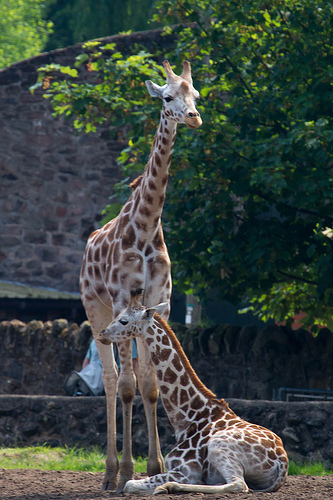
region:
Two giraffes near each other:
[76, 52, 291, 498]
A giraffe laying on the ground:
[95, 283, 294, 496]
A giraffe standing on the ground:
[77, 59, 188, 490]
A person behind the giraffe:
[73, 305, 143, 402]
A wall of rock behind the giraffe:
[5, 44, 162, 315]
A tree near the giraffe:
[47, 33, 331, 341]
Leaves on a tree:
[229, 109, 326, 301]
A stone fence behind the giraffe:
[4, 302, 330, 483]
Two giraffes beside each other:
[46, 37, 282, 497]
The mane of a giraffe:
[145, 305, 227, 401]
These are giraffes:
[45, 70, 209, 495]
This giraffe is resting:
[88, 314, 288, 480]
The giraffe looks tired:
[97, 315, 178, 354]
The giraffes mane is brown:
[153, 316, 231, 407]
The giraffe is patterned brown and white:
[157, 365, 238, 476]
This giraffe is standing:
[70, 68, 190, 271]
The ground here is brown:
[9, 464, 69, 497]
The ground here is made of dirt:
[33, 468, 83, 498]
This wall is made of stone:
[6, 336, 53, 403]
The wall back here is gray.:
[10, 133, 94, 277]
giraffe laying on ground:
[102, 301, 287, 492]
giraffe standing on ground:
[97, 67, 200, 485]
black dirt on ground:
[2, 469, 331, 494]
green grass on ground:
[2, 444, 321, 475]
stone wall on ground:
[4, 397, 330, 458]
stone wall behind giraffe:
[5, 325, 328, 402]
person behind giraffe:
[80, 340, 140, 391]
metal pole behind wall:
[274, 385, 331, 398]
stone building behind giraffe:
[0, 57, 196, 289]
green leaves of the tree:
[63, 70, 331, 324]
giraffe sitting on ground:
[95, 283, 288, 498]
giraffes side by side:
[80, 49, 295, 499]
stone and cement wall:
[0, 305, 332, 469]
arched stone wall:
[0, 26, 307, 311]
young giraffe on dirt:
[92, 287, 294, 497]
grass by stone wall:
[6, 391, 330, 479]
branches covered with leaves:
[65, 4, 331, 323]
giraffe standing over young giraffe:
[78, 61, 292, 491]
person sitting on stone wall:
[69, 315, 166, 409]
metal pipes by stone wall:
[264, 376, 331, 403]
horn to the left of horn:
[161, 59, 174, 75]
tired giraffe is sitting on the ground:
[95, 286, 288, 494]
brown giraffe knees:
[123, 388, 133, 402]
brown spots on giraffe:
[163, 368, 177, 383]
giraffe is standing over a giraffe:
[80, 58, 202, 492]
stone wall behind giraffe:
[0, 394, 331, 460]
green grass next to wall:
[2, 445, 166, 472]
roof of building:
[1, 278, 87, 323]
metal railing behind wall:
[277, 387, 332, 401]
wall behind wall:
[2, 319, 89, 393]